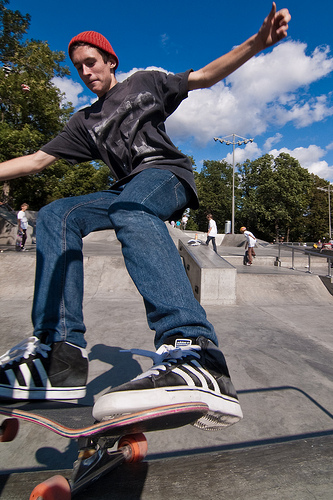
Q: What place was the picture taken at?
A: It was taken at the park.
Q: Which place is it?
A: It is a park.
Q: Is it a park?
A: Yes, it is a park.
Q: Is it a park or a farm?
A: It is a park.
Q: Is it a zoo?
A: No, it is a park.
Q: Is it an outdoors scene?
A: Yes, it is outdoors.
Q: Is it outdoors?
A: Yes, it is outdoors.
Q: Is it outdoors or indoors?
A: It is outdoors.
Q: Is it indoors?
A: No, it is outdoors.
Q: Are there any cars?
A: No, there are no cars.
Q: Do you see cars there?
A: No, there are no cars.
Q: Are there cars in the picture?
A: No, there are no cars.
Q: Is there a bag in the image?
A: No, there are no bags.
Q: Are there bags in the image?
A: No, there are no bags.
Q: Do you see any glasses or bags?
A: No, there are no bags or glasses.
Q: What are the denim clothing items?
A: The clothing items are jeans.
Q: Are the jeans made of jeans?
A: Yes, the jeans are made of jeans.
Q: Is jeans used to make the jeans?
A: Yes, the jeans are made of jeans.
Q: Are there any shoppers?
A: No, there are no shoppers.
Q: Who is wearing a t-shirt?
A: The boy is wearing a t-shirt.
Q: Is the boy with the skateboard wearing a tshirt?
A: Yes, the boy is wearing a tshirt.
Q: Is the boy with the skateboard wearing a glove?
A: No, the boy is wearing a tshirt.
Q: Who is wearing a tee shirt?
A: The boy is wearing a tee shirt.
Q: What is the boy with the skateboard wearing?
A: The boy is wearing a tee shirt.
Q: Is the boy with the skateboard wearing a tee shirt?
A: Yes, the boy is wearing a tee shirt.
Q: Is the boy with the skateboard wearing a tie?
A: No, the boy is wearing a tee shirt.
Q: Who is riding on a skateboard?
A: The boy is riding on a skateboard.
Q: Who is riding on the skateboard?
A: The boy is riding on a skateboard.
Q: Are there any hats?
A: Yes, there is a hat.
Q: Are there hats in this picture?
A: Yes, there is a hat.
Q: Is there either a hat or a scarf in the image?
A: Yes, there is a hat.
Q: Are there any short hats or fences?
A: Yes, there is a short hat.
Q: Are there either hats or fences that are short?
A: Yes, the hat is short.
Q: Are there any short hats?
A: Yes, there is a short hat.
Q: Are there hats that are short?
A: Yes, there is a hat that is short.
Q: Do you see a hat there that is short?
A: Yes, there is a hat that is short.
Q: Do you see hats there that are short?
A: Yes, there is a hat that is short.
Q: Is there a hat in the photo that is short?
A: Yes, there is a hat that is short.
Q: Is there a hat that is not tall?
A: Yes, there is a short hat.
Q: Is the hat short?
A: Yes, the hat is short.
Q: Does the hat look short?
A: Yes, the hat is short.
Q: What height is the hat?
A: The hat is short.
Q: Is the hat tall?
A: No, the hat is short.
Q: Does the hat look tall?
A: No, the hat is short.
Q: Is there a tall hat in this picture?
A: No, there is a hat but it is short.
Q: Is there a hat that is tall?
A: No, there is a hat but it is short.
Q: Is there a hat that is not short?
A: No, there is a hat but it is short.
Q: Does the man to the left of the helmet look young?
A: Yes, the man is young.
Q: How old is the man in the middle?
A: The man is young.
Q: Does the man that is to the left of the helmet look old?
A: No, the man is young.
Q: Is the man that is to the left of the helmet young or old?
A: The man is young.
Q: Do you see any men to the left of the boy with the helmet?
A: Yes, there is a man to the left of the boy.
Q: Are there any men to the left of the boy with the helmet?
A: Yes, there is a man to the left of the boy.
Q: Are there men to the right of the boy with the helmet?
A: No, the man is to the left of the boy.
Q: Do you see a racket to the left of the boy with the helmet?
A: No, there is a man to the left of the boy.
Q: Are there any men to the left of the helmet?
A: Yes, there is a man to the left of the helmet.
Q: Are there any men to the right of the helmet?
A: No, the man is to the left of the helmet.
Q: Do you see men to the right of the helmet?
A: No, the man is to the left of the helmet.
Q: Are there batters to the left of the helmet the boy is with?
A: No, there is a man to the left of the helmet.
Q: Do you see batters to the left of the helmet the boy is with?
A: No, there is a man to the left of the helmet.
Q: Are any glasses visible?
A: No, there are no glasses.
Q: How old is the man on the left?
A: The man is young.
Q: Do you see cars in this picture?
A: No, there are no cars.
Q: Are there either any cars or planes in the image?
A: No, there are no cars or planes.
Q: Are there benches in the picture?
A: No, there are no benches.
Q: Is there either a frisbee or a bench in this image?
A: No, there are no benches or frisbees.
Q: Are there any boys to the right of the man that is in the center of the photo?
A: Yes, there is a boy to the right of the man.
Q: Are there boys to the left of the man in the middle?
A: No, the boy is to the right of the man.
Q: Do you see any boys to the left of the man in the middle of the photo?
A: No, the boy is to the right of the man.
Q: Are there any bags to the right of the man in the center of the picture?
A: No, there is a boy to the right of the man.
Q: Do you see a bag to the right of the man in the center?
A: No, there is a boy to the right of the man.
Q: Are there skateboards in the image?
A: Yes, there is a skateboard.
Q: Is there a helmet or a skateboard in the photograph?
A: Yes, there is a skateboard.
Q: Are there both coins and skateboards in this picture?
A: No, there is a skateboard but no coins.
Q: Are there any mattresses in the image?
A: No, there are no mattresses.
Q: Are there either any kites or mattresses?
A: No, there are no mattresses or kites.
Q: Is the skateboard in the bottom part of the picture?
A: Yes, the skateboard is in the bottom of the image.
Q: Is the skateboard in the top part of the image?
A: No, the skateboard is in the bottom of the image.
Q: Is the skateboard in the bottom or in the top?
A: The skateboard is in the bottom of the image.